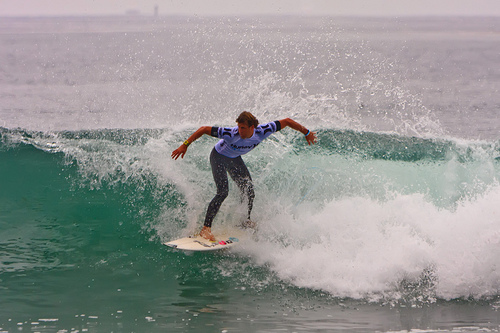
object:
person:
[172, 110, 317, 240]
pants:
[204, 146, 254, 225]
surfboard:
[162, 227, 259, 251]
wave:
[14, 126, 500, 302]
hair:
[235, 111, 259, 129]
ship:
[124, 6, 143, 16]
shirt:
[208, 120, 283, 157]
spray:
[156, 40, 433, 129]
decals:
[195, 236, 239, 247]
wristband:
[183, 140, 190, 147]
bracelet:
[304, 129, 311, 137]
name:
[230, 143, 255, 149]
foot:
[200, 225, 216, 242]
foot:
[239, 217, 258, 231]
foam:
[281, 189, 497, 296]